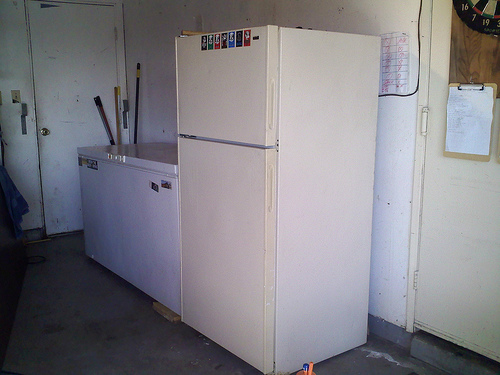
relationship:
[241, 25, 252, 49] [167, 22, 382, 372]
sticker on fridge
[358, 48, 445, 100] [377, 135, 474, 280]
paper on wall